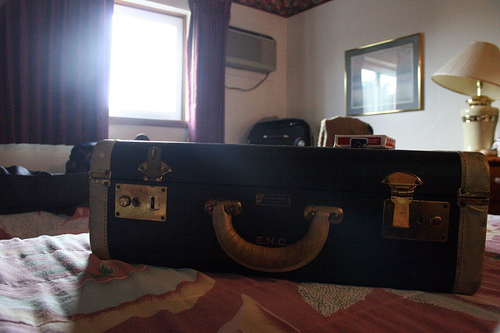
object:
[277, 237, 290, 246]
c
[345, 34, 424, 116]
picture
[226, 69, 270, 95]
cord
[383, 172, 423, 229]
latch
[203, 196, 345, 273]
handle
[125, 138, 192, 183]
open latch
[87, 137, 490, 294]
case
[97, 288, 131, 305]
blue color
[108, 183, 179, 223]
lock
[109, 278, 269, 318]
quilt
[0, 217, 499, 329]
bedspread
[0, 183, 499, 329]
bed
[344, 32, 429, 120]
decor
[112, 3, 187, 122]
window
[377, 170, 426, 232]
metal latch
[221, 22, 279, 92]
air conditioner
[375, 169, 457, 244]
metal lock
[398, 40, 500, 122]
lampshade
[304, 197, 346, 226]
screw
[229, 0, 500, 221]
wall